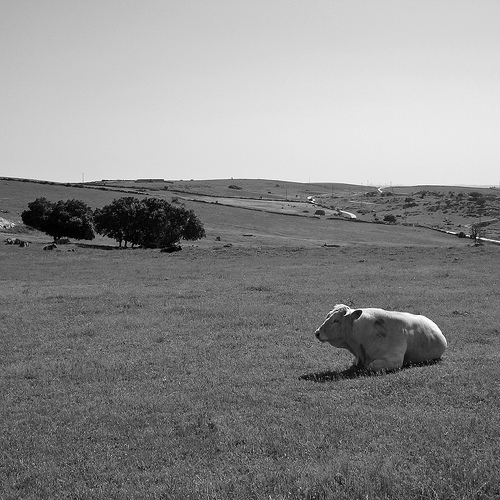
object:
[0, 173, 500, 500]
grass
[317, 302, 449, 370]
cow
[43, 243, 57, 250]
cow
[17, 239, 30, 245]
cow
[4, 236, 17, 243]
cow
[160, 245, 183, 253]
cow